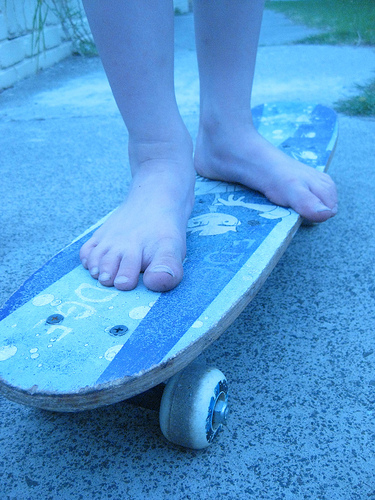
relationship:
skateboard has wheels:
[1, 96, 343, 447] [160, 369, 237, 444]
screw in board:
[47, 310, 63, 329] [1, 96, 343, 447]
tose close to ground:
[261, 133, 340, 220] [220, 3, 373, 452]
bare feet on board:
[199, 128, 341, 227] [1, 96, 343, 447]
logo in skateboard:
[184, 205, 243, 238] [1, 96, 343, 447]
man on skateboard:
[78, 0, 342, 296] [1, 96, 343, 447]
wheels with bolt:
[160, 369, 237, 444] [47, 310, 63, 329]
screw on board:
[47, 310, 63, 329] [1, 96, 343, 447]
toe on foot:
[304, 188, 329, 220] [199, 128, 341, 227]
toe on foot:
[304, 188, 329, 220] [78, 148, 198, 293]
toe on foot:
[304, 188, 329, 220] [76, 164, 195, 288]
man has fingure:
[78, 238, 184, 298] [77, 236, 179, 295]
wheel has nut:
[160, 369, 237, 444] [218, 403, 234, 424]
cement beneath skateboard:
[5, 10, 360, 492] [1, 96, 343, 447]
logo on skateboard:
[183, 194, 253, 243] [1, 96, 343, 447]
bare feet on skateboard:
[193, 128, 341, 222] [1, 96, 343, 447]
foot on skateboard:
[78, 137, 195, 293] [1, 96, 343, 447]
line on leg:
[130, 137, 176, 145] [79, 4, 196, 290]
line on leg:
[132, 153, 150, 179] [79, 4, 196, 290]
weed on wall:
[63, 13, 97, 65] [1, 0, 99, 91]